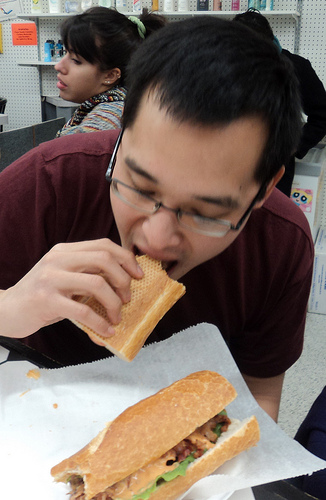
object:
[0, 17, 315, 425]
man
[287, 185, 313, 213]
cartoon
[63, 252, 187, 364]
sandwich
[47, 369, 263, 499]
sandwich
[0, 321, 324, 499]
paper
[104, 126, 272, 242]
glasses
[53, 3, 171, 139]
woman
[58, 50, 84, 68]
eyes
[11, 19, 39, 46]
sign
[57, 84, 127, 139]
sweater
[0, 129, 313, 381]
shirt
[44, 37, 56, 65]
toiletry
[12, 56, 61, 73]
shelf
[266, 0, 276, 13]
bottle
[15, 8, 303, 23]
shelf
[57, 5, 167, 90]
hair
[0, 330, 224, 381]
edge